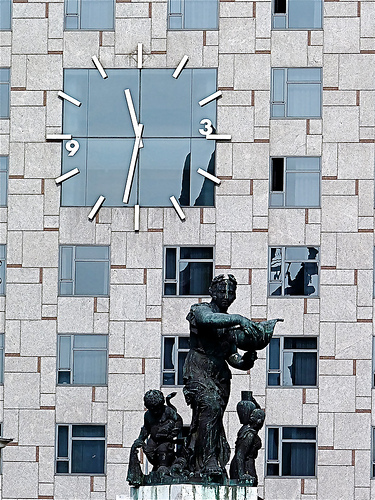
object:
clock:
[42, 42, 232, 236]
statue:
[183, 273, 266, 481]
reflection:
[63, 67, 217, 207]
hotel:
[0, 0, 375, 500]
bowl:
[230, 319, 284, 352]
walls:
[317, 0, 375, 500]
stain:
[205, 397, 207, 399]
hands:
[121, 87, 142, 149]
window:
[285, 81, 321, 119]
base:
[137, 484, 257, 500]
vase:
[240, 391, 251, 401]